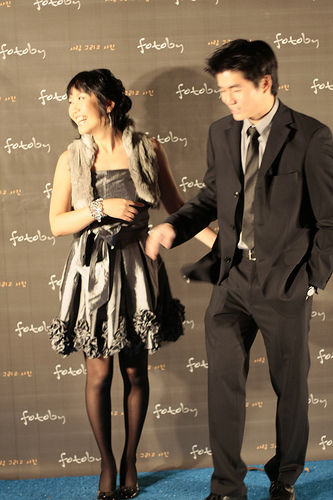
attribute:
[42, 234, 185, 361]
dress — nice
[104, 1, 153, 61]
backdrop — black, red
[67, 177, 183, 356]
dress — silver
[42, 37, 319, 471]
people — dressed fancy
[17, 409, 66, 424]
text — white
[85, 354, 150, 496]
hosiery — sexy